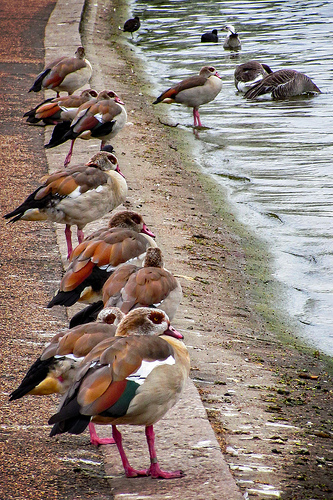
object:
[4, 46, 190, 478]
bird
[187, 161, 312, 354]
mold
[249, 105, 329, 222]
water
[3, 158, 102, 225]
feather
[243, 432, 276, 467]
snow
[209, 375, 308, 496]
ground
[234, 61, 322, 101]
duck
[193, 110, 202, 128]
leg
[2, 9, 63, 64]
walk way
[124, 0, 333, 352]
lake